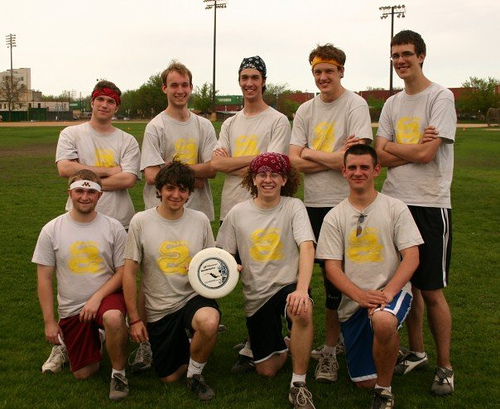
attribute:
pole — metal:
[211, 2, 218, 94]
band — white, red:
[240, 60, 256, 69]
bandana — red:
[247, 152, 290, 177]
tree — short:
[461, 72, 491, 124]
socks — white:
[193, 358, 209, 372]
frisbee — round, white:
[172, 240, 278, 321]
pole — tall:
[3, 29, 17, 106]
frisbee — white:
[180, 234, 250, 309]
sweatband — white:
[65, 177, 105, 195]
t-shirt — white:
[30, 207, 124, 330]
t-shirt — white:
[120, 197, 220, 322]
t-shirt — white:
[217, 189, 322, 319]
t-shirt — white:
[315, 185, 437, 322]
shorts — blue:
[319, 276, 467, 370]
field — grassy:
[2, 126, 499, 403]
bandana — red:
[238, 53, 263, 78]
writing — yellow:
[245, 226, 287, 263]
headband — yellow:
[306, 52, 348, 73]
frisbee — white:
[181, 241, 243, 300]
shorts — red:
[47, 291, 127, 372]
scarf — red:
[242, 147, 296, 177]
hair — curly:
[233, 160, 299, 195]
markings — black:
[197, 251, 229, 290]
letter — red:
[82, 177, 98, 186]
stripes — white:
[386, 286, 415, 324]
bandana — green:
[235, 57, 275, 71]